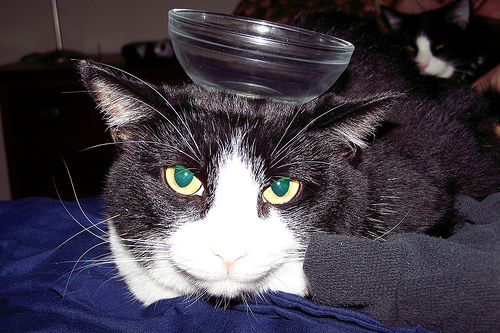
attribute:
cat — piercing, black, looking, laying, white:
[16, 60, 413, 313]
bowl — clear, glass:
[158, 16, 345, 103]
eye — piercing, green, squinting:
[138, 145, 315, 224]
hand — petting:
[466, 69, 494, 109]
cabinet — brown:
[14, 8, 178, 51]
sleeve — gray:
[405, 8, 430, 17]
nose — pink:
[207, 235, 260, 289]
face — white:
[124, 130, 325, 255]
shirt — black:
[395, 243, 457, 291]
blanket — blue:
[19, 202, 70, 264]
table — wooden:
[46, 54, 73, 76]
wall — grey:
[24, 13, 68, 47]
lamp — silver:
[115, 30, 174, 77]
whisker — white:
[36, 193, 162, 300]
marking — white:
[280, 266, 321, 292]